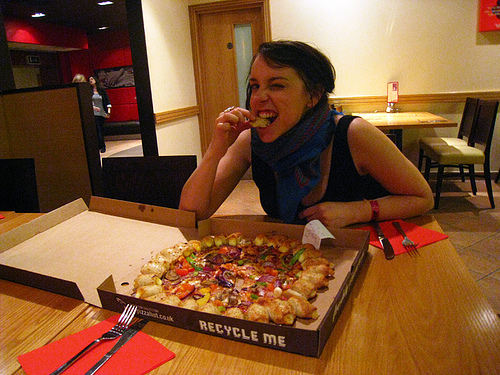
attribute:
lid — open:
[0, 194, 195, 302]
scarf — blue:
[242, 137, 339, 230]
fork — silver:
[393, 217, 419, 254]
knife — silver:
[373, 218, 395, 260]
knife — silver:
[76, 317, 152, 372]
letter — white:
[197, 318, 207, 331]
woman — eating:
[217, 53, 370, 205]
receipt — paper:
[306, 226, 331, 245]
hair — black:
[259, 39, 337, 100]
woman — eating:
[171, 34, 428, 233]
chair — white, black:
[427, 96, 499, 208]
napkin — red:
[121, 347, 143, 359]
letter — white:
[231, 325, 288, 348]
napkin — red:
[22, 317, 177, 373]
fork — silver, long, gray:
[50, 302, 137, 373]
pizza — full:
[135, 230, 336, 322]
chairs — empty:
[213, 76, 450, 258]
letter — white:
[193, 318, 295, 361]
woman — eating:
[178, 40, 434, 228]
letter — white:
[190, 320, 210, 337]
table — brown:
[325, 95, 455, 137]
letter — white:
[279, 327, 292, 352]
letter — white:
[261, 331, 276, 346]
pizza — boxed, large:
[136, 225, 335, 329]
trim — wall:
[144, 100, 220, 133]